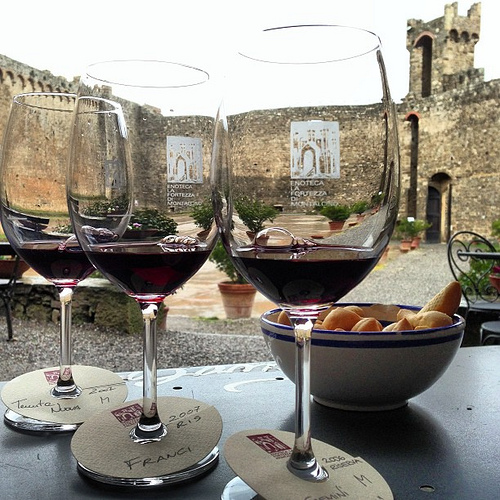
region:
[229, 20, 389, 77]
the mouth of a wine glass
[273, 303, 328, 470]
the stem of a wine glass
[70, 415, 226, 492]
the base of a wine glass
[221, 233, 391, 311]
red wine in the glass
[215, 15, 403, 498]
a wine glass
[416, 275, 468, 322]
bread in the bowl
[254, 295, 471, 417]
a white and blue bowl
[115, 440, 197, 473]
writing on the paper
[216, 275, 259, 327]
a brown pot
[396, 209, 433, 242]
green plants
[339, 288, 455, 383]
bowl filled with cookies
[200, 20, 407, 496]
a clear wine glass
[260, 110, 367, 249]
white writing on the glass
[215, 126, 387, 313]
red wine in the glass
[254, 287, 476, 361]
bread in a bowl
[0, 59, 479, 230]
a huge wall made of rock and brick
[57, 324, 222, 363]
grey gravel on the floor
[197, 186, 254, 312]
a potted plant in the background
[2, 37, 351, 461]
3 glasses of red wine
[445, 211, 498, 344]
a black iron chair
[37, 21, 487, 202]
the day is overcast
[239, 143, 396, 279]
glass with liquid in it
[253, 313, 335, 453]
handle of the glass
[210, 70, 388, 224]
clear drinking glass on table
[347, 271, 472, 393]
food in a bowl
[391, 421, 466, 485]
table beneath the bowl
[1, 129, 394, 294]
three wine glasses next to each other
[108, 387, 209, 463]
bottom part of glass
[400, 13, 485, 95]
structure in the background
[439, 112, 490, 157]
brick building behind glasses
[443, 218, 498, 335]
chair behind wine glasses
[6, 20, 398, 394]
three wine glasses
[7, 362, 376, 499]
circular tags with writing on them at base of glasses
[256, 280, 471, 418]
large blue and white bowl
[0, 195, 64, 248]
bench seen through wine glass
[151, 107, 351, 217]
etched logos on wine glasses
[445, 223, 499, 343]
wrought iron chair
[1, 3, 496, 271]
ancient building behind wine glasses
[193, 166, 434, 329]
potted plants set in a line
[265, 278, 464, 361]
food in bowl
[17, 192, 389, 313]
dark red liquid in wine glasses